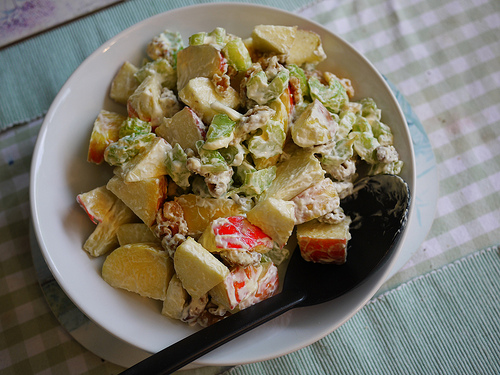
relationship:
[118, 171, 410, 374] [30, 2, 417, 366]
spoon in bowl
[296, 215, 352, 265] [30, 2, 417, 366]
apple in bowl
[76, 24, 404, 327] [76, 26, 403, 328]
dressing on food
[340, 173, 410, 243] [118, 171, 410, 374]
dressing on spoon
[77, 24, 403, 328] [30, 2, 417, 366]
assorted vegetables in bowl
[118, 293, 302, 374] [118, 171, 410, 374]
handle on spoon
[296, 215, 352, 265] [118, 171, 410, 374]
apple on spoon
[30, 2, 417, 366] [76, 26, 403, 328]
bowl under food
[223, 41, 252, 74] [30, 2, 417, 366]
grape in bowl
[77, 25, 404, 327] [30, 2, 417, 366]
apple salad in bowl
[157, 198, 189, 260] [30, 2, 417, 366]
pecan in bowl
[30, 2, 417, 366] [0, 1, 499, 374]
bowl on tablecloth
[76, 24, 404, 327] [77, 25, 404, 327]
dressing on apple salad